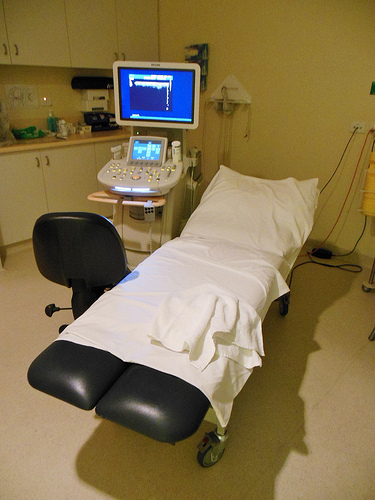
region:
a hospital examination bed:
[24, 162, 323, 453]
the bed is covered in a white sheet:
[49, 165, 321, 428]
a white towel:
[143, 271, 272, 376]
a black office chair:
[21, 203, 134, 341]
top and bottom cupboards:
[1, 1, 160, 256]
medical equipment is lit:
[88, 53, 203, 253]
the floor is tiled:
[0, 236, 373, 498]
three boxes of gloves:
[180, 39, 211, 97]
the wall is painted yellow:
[151, 0, 372, 263]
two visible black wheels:
[192, 283, 289, 472]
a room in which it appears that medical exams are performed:
[0, 0, 363, 495]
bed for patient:
[63, 171, 291, 434]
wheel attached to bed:
[188, 418, 234, 470]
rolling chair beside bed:
[23, 196, 137, 336]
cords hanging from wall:
[294, 107, 372, 273]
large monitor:
[111, 60, 201, 125]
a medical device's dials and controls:
[96, 136, 181, 226]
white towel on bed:
[150, 285, 270, 375]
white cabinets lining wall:
[5, 2, 155, 234]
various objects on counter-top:
[0, 99, 98, 151]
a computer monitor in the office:
[111, 60, 199, 128]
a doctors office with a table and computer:
[0, 1, 369, 488]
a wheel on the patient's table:
[197, 437, 222, 465]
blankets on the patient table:
[103, 173, 313, 418]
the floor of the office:
[1, 246, 373, 498]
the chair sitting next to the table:
[30, 214, 128, 337]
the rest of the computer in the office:
[100, 138, 178, 199]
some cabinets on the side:
[6, 141, 125, 244]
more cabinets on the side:
[0, 0, 165, 68]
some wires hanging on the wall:
[317, 124, 372, 256]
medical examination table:
[30, 159, 329, 464]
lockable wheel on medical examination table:
[192, 424, 235, 471]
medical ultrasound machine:
[82, 49, 218, 265]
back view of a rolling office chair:
[19, 200, 141, 327]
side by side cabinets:
[0, 0, 168, 73]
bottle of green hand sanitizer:
[40, 105, 62, 140]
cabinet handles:
[24, 150, 62, 179]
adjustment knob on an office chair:
[32, 272, 82, 334]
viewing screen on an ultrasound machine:
[109, 56, 209, 137]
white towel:
[143, 276, 284, 381]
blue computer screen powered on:
[112, 60, 200, 128]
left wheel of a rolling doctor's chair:
[199, 431, 227, 469]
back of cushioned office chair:
[32, 210, 141, 340]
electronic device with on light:
[39, 89, 51, 107]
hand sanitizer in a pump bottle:
[47, 109, 55, 130]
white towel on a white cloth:
[149, 284, 265, 373]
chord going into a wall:
[317, 120, 358, 192]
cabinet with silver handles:
[1, 0, 160, 69]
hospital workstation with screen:
[87, 62, 199, 252]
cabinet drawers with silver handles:
[1, 114, 132, 246]